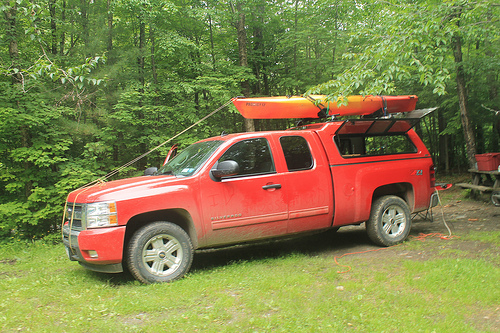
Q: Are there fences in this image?
A: No, there are no fences.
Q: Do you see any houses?
A: No, there are no houses.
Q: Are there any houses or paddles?
A: No, there are no houses or paddles.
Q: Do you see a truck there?
A: Yes, there is a truck.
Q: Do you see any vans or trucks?
A: Yes, there is a truck.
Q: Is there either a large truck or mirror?
A: Yes, there is a large truck.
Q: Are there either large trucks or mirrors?
A: Yes, there is a large truck.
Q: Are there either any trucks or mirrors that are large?
A: Yes, the truck is large.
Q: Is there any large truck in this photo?
A: Yes, there is a large truck.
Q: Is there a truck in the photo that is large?
A: Yes, there is a truck that is large.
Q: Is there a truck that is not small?
A: Yes, there is a large truck.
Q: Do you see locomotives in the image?
A: No, there are no locomotives.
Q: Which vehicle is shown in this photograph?
A: The vehicle is a truck.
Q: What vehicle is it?
A: The vehicle is a truck.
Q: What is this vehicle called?
A: This is a truck.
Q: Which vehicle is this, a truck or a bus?
A: This is a truck.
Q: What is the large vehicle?
A: The vehicle is a truck.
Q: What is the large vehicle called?
A: The vehicle is a truck.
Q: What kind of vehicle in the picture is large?
A: The vehicle is a truck.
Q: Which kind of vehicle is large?
A: The vehicle is a truck.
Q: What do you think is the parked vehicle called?
A: The vehicle is a truck.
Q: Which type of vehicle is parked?
A: The vehicle is a truck.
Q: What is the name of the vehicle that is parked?
A: The vehicle is a truck.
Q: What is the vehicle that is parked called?
A: The vehicle is a truck.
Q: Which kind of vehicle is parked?
A: The vehicle is a truck.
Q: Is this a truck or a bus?
A: This is a truck.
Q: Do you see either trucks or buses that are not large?
A: No, there is a truck but it is large.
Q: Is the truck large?
A: Yes, the truck is large.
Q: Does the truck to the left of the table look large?
A: Yes, the truck is large.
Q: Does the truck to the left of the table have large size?
A: Yes, the truck is large.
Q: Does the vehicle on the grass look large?
A: Yes, the truck is large.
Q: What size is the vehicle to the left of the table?
A: The truck is large.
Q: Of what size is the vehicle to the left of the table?
A: The truck is large.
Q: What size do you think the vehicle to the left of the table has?
A: The truck has large size.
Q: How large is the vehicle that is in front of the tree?
A: The truck is large.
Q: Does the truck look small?
A: No, the truck is large.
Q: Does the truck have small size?
A: No, the truck is large.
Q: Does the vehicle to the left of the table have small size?
A: No, the truck is large.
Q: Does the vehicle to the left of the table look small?
A: No, the truck is large.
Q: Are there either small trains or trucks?
A: No, there is a truck but it is large.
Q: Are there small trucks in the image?
A: No, there is a truck but it is large.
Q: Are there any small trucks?
A: No, there is a truck but it is large.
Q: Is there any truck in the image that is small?
A: No, there is a truck but it is large.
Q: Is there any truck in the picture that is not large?
A: No, there is a truck but it is large.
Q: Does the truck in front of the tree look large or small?
A: The truck is large.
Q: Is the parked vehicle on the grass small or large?
A: The truck is large.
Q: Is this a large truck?
A: Yes, this is a large truck.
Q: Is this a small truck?
A: No, this is a large truck.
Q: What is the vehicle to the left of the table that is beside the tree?
A: The vehicle is a truck.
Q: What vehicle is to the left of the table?
A: The vehicle is a truck.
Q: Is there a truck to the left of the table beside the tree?
A: Yes, there is a truck to the left of the table.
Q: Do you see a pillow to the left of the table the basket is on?
A: No, there is a truck to the left of the table.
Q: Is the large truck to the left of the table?
A: Yes, the truck is to the left of the table.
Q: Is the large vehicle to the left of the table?
A: Yes, the truck is to the left of the table.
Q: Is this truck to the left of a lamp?
A: No, the truck is to the left of the table.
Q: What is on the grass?
A: The truck is on the grass.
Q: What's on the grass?
A: The truck is on the grass.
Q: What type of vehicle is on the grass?
A: The vehicle is a truck.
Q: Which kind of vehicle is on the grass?
A: The vehicle is a truck.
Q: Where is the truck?
A: The truck is on the grass.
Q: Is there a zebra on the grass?
A: No, there is a truck on the grass.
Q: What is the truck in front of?
A: The truck is in front of the tree.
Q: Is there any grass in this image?
A: Yes, there is grass.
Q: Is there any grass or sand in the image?
A: Yes, there is grass.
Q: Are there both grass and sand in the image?
A: No, there is grass but no sand.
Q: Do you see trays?
A: No, there are no trays.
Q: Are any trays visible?
A: No, there are no trays.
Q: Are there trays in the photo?
A: No, there are no trays.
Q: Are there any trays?
A: No, there are no trays.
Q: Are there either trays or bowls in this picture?
A: No, there are no trays or bowls.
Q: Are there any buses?
A: No, there are no buses.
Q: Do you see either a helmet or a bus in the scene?
A: No, there are no buses or helmets.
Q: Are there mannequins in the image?
A: No, there are no mannequins.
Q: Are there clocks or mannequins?
A: No, there are no mannequins or clocks.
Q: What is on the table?
A: The basket is on the table.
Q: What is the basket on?
A: The basket is on the table.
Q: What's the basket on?
A: The basket is on the table.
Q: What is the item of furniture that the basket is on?
A: The piece of furniture is a table.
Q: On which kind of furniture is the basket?
A: The basket is on the table.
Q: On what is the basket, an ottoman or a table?
A: The basket is on a table.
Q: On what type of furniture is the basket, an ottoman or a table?
A: The basket is on a table.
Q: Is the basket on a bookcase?
A: No, the basket is on a table.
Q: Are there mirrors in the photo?
A: Yes, there is a mirror.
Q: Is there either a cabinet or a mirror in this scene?
A: Yes, there is a mirror.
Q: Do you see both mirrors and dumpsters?
A: No, there is a mirror but no dumpsters.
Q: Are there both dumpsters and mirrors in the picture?
A: No, there is a mirror but no dumpsters.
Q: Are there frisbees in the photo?
A: No, there are no frisbees.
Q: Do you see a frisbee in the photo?
A: No, there are no frisbees.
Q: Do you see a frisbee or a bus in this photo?
A: No, there are no frisbees or buses.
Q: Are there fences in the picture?
A: No, there are no fences.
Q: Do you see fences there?
A: No, there are no fences.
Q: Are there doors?
A: Yes, there is a door.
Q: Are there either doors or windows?
A: Yes, there is a door.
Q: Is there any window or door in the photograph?
A: Yes, there is a door.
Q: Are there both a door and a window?
A: Yes, there are both a door and a window.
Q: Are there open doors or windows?
A: Yes, there is an open door.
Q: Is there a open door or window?
A: Yes, there is an open door.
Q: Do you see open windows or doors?
A: Yes, there is an open door.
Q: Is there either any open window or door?
A: Yes, there is an open door.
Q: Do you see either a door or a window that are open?
A: Yes, the door is open.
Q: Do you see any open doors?
A: Yes, there is an open door.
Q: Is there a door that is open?
A: Yes, there is a door that is open.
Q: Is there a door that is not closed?
A: Yes, there is a open door.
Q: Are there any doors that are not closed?
A: Yes, there is a open door.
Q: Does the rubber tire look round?
A: Yes, the tire is round.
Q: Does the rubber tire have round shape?
A: Yes, the tire is round.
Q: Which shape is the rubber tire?
A: The tire is round.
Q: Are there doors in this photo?
A: Yes, there is a door.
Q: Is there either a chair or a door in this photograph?
A: Yes, there is a door.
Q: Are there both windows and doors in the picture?
A: Yes, there are both a door and a window.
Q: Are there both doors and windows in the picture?
A: Yes, there are both a door and a window.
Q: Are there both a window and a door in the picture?
A: Yes, there are both a door and a window.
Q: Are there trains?
A: No, there are no trains.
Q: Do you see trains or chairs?
A: No, there are no trains or chairs.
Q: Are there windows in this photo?
A: Yes, there is a window.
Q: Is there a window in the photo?
A: Yes, there is a window.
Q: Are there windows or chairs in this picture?
A: Yes, there is a window.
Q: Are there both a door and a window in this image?
A: Yes, there are both a window and a door.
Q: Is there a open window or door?
A: Yes, there is an open window.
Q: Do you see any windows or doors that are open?
A: Yes, the window is open.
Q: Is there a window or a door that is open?
A: Yes, the window is open.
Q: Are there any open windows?
A: Yes, there is an open window.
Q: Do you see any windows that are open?
A: Yes, there is a window that is open.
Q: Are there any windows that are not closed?
A: Yes, there is a open window.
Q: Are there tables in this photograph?
A: Yes, there is a table.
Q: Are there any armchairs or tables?
A: Yes, there is a table.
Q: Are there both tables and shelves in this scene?
A: No, there is a table but no shelves.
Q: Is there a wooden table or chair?
A: Yes, there is a wood table.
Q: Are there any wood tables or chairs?
A: Yes, there is a wood table.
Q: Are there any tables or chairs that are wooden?
A: Yes, the table is wooden.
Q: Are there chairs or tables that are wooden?
A: Yes, the table is wooden.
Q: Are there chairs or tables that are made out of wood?
A: Yes, the table is made of wood.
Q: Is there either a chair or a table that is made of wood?
A: Yes, the table is made of wood.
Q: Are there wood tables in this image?
A: Yes, there is a wood table.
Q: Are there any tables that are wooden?
A: Yes, there is a table that is wooden.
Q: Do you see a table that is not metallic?
A: Yes, there is a wooden table.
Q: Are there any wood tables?
A: Yes, there is a table that is made of wood.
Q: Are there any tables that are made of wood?
A: Yes, there is a table that is made of wood.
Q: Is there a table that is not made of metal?
A: Yes, there is a table that is made of wood.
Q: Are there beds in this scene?
A: No, there are no beds.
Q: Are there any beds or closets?
A: No, there are no beds or closets.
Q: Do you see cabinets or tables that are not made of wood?
A: No, there is a table but it is made of wood.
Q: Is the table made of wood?
A: Yes, the table is made of wood.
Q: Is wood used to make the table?
A: Yes, the table is made of wood.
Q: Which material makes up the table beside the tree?
A: The table is made of wood.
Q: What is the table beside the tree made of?
A: The table is made of wood.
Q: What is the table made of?
A: The table is made of wood.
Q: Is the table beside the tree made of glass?
A: No, the table is made of wood.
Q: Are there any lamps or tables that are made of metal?
A: No, there is a table but it is made of wood.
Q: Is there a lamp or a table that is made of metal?
A: No, there is a table but it is made of wood.